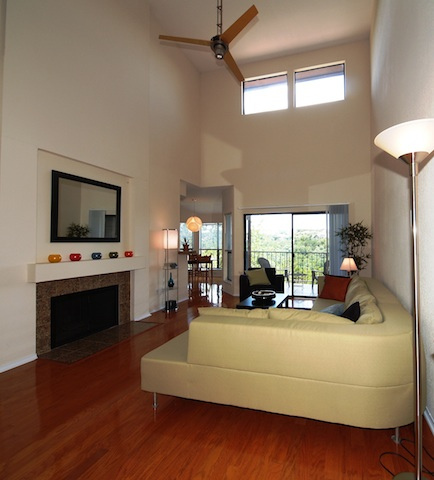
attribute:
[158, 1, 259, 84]
ceiling fan — wooden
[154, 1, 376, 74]
ceiling — white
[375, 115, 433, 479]
floor lamp — silver, on, tall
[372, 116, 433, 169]
lamp shade — white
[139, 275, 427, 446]
sectional — white, leather, tan, cream, large, beige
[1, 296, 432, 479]
floor — hardwood, dark brown, shiny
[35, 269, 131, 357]
fire place — brick, stone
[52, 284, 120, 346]
screen — black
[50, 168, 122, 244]
frame — black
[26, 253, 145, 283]
mantel — white, wooden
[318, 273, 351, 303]
pillow — red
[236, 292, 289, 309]
coffee table — dark brown, dark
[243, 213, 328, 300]
sliding door — glass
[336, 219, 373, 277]
plant — green, large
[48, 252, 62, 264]
candle — yellow, glass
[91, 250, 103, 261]
candle — blue, glass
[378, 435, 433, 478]
cord — black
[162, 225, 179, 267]
lamp — on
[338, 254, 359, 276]
lamp — on, lit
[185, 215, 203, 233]
light — on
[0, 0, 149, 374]
wall — white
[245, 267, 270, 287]
pillow — white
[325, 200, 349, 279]
curtain — blue, long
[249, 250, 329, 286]
railing — exterior